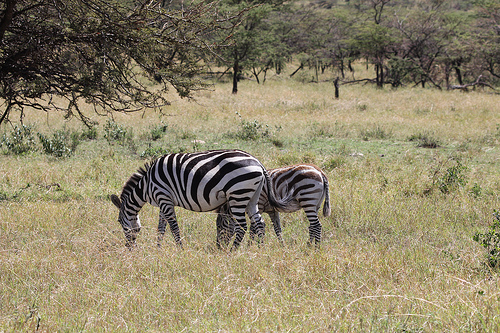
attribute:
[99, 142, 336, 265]
zebras — eating, standing, striped, black, white, bending, facing, grazing, brown, young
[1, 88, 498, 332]
grass — low, brownish, green, tall, brown, yellow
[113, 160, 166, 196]
mane — long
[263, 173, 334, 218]
tail — black, hanging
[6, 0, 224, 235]
tree — tall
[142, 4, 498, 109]
trees — green, bare